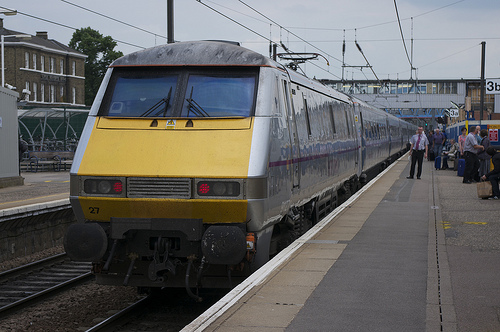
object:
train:
[60, 39, 427, 302]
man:
[405, 125, 429, 181]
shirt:
[406, 132, 429, 151]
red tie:
[411, 133, 423, 151]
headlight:
[193, 178, 210, 196]